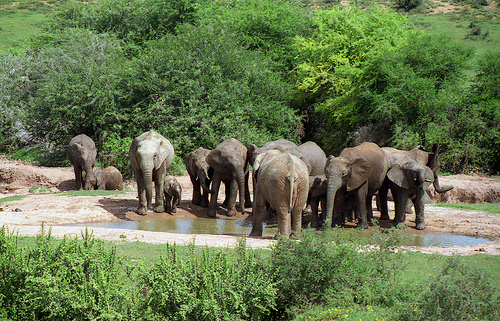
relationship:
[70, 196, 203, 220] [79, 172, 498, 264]
dirt around pool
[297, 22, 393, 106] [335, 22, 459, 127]
leaves on tree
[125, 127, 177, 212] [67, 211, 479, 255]
elephant in water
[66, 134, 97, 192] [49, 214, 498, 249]
elephant at pool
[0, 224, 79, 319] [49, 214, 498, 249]
bush near pool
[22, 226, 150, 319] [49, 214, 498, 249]
bush near pool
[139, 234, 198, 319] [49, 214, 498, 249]
bush near pool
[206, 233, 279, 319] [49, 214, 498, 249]
bush near pool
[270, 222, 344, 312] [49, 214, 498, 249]
bush near pool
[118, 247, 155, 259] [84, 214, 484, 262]
grass near watering hole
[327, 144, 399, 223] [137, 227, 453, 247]
elephant drinking water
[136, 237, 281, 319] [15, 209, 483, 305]
bushes in forefront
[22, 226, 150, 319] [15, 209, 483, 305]
bush in forefront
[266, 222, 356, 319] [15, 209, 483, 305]
bush in forefront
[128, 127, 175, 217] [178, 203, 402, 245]
elephant in water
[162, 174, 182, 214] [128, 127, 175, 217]
baby elephant by elephant